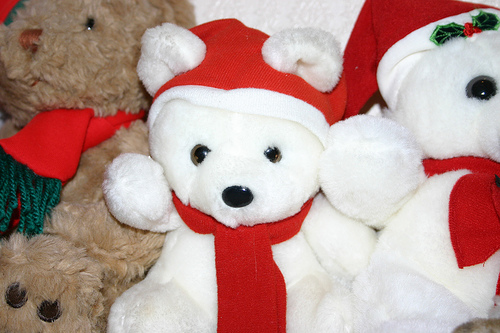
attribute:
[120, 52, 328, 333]
toy — white, stuffed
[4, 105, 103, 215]
scarf — green, red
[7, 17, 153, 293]
bear — brown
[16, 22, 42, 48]
nose — brown, black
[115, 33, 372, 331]
middle bear — white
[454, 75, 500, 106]
eye — black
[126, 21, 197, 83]
ear — white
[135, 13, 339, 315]
teddy bar — white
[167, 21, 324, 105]
hat — red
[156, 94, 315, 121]
rim — white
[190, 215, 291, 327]
scarf — red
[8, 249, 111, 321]
foot — brown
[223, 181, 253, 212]
nose — black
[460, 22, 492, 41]
ribbon — red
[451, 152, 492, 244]
shawl — red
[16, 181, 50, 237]
marvin — edge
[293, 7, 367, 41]
pocket — red